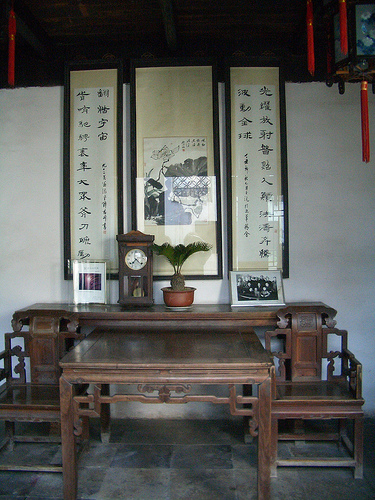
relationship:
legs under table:
[56, 376, 276, 500] [52, 322, 285, 499]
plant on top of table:
[154, 241, 214, 312] [13, 298, 334, 340]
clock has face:
[115, 227, 157, 310] [120, 248, 151, 275]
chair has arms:
[10, 309, 365, 482] [2, 349, 365, 394]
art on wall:
[58, 60, 293, 285] [8, 59, 370, 346]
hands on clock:
[126, 258, 144, 269] [115, 227, 157, 310]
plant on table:
[154, 241, 214, 312] [52, 322, 285, 499]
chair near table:
[10, 309, 365, 482] [52, 322, 285, 499]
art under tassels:
[58, 60, 293, 285] [5, 6, 373, 172]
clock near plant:
[115, 227, 157, 310] [154, 241, 214, 312]